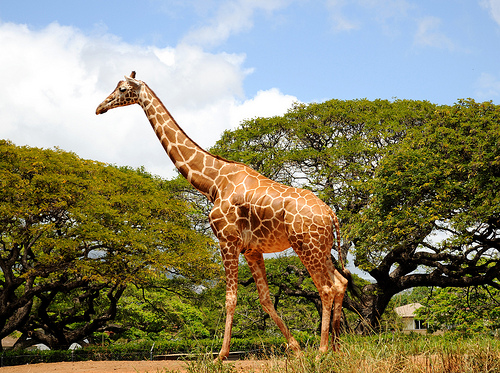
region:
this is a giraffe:
[121, 65, 335, 315]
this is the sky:
[301, 26, 434, 83]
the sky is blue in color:
[328, 32, 385, 79]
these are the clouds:
[31, 56, 68, 119]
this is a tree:
[363, 127, 458, 214]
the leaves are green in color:
[363, 158, 470, 247]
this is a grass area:
[382, 325, 424, 351]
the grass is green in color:
[383, 325, 417, 345]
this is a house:
[394, 303, 417, 329]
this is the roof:
[400, 300, 410, 315]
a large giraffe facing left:
[87, 68, 362, 358]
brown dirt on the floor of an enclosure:
[18, 352, 180, 372]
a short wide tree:
[3, 141, 206, 357]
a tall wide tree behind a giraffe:
[238, 100, 491, 357]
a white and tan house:
[396, 295, 443, 342]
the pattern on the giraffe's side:
[229, 180, 283, 232]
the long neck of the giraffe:
[148, 103, 211, 178]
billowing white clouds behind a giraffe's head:
[37, 27, 247, 141]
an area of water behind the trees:
[32, 339, 95, 353]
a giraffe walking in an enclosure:
[62, 27, 491, 372]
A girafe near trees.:
[80, 67, 428, 360]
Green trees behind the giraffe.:
[0, 97, 496, 352]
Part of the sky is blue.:
[265, 30, 421, 73]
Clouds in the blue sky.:
[150, 30, 391, 85]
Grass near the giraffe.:
[201, 325, 496, 371]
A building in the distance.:
[390, 298, 447, 334]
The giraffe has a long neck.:
[135, 97, 240, 193]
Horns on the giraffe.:
[111, 65, 146, 85]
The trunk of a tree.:
[361, 231, 427, 327]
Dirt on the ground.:
[32, 362, 123, 372]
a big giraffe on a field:
[86, 65, 362, 365]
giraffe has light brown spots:
[83, 67, 375, 359]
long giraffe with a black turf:
[324, 204, 364, 308]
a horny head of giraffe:
[88, 61, 152, 123]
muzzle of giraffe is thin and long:
[86, 89, 120, 122]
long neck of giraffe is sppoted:
[136, 89, 221, 195]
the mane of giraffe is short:
[147, 73, 252, 171]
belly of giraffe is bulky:
[246, 219, 289, 266]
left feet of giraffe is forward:
[202, 246, 243, 368]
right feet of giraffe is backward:
[250, 256, 315, 361]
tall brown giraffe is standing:
[95, 70, 365, 362]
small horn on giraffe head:
[128, 69, 136, 79]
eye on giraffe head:
[118, 86, 128, 93]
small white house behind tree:
[390, 300, 435, 330]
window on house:
[412, 316, 427, 326]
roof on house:
[393, 300, 428, 315]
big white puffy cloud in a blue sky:
[0, 21, 306, 179]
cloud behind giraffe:
[0, 21, 306, 178]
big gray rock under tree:
[23, 341, 53, 351]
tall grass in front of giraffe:
[181, 317, 498, 371]